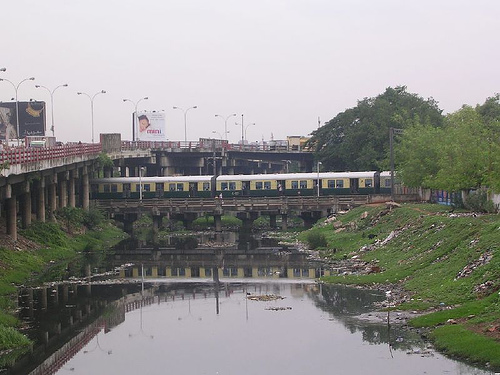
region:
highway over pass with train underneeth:
[0, 68, 498, 373]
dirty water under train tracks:
[2, 218, 488, 373]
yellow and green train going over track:
[92, 172, 402, 194]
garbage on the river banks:
[330, 251, 470, 372]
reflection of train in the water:
[75, 253, 337, 283]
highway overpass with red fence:
[2, 146, 317, 176]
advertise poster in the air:
[135, 112, 169, 139]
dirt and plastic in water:
[242, 293, 295, 310]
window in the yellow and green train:
[169, 183, 186, 191]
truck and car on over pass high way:
[25, 135, 60, 150]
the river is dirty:
[257, 218, 337, 287]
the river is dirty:
[318, 232, 367, 284]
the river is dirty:
[218, 270, 299, 325]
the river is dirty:
[92, 234, 172, 287]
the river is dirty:
[211, 222, 298, 257]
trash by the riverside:
[328, 202, 393, 256]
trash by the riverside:
[367, 214, 450, 268]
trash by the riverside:
[437, 227, 489, 304]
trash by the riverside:
[334, 206, 389, 236]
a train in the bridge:
[115, 165, 387, 214]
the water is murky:
[123, 298, 202, 355]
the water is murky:
[239, 271, 338, 342]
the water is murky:
[165, 213, 266, 305]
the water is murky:
[150, 255, 302, 346]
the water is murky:
[129, 290, 264, 366]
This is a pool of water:
[16, 220, 447, 369]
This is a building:
[0, 136, 107, 230]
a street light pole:
[73, 83, 108, 157]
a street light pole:
[123, 85, 149, 147]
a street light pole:
[169, 102, 201, 142]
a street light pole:
[212, 106, 240, 146]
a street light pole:
[34, 76, 69, 144]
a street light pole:
[1, 66, 38, 138]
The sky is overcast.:
[3, 5, 497, 150]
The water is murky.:
[17, 210, 454, 372]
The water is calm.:
[33, 214, 433, 374]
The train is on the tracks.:
[83, 167, 415, 213]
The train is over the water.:
[93, 169, 398, 206]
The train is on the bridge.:
[83, 169, 411, 216]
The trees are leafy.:
[303, 78, 489, 190]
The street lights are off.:
[0, 67, 267, 157]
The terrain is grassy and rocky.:
[293, 189, 498, 355]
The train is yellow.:
[90, 171, 392, 210]